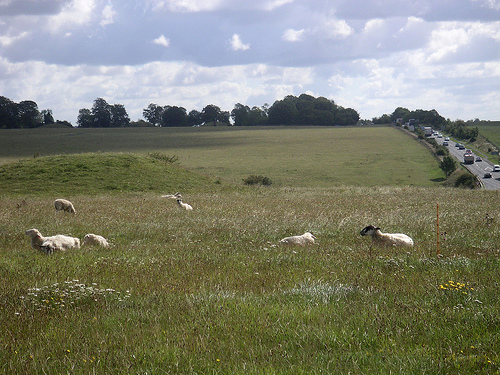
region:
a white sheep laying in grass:
[25, 225, 82, 260]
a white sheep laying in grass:
[276, 228, 317, 250]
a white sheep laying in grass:
[356, 222, 417, 253]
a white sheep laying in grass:
[170, 196, 194, 213]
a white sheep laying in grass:
[51, 198, 73, 217]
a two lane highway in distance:
[416, 116, 498, 191]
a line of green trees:
[1, 90, 362, 135]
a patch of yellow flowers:
[432, 274, 474, 302]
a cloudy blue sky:
[3, 4, 498, 114]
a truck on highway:
[460, 151, 475, 167]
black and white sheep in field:
[25, 227, 80, 257]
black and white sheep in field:
[85, 224, 106, 254]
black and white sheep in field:
[46, 189, 73, 215]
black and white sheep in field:
[162, 184, 203, 234]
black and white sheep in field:
[266, 220, 318, 256]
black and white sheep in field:
[349, 218, 409, 258]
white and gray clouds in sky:
[24, 5, 463, 82]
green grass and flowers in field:
[20, 265, 338, 346]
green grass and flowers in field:
[42, 131, 381, 188]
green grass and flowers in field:
[138, 228, 243, 312]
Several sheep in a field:
[33, 179, 419, 294]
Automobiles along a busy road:
[398, 112, 498, 190]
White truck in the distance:
[463, 149, 473, 167]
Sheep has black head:
[358, 219, 381, 232]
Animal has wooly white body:
[21, 221, 91, 253]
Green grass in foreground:
[130, 237, 496, 373]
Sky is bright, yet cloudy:
[12, 2, 495, 91]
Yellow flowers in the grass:
[436, 276, 470, 298]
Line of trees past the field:
[85, 92, 375, 126]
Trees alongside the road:
[417, 101, 482, 141]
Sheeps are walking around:
[22, 156, 457, 328]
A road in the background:
[379, 99, 499, 189]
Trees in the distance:
[28, 59, 489, 189]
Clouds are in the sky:
[26, 12, 463, 142]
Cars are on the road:
[386, 88, 498, 196]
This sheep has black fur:
[349, 200, 427, 265]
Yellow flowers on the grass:
[411, 257, 485, 322]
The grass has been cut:
[38, 176, 440, 351]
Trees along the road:
[363, 73, 485, 207]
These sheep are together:
[18, 219, 192, 273]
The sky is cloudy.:
[38, 2, 470, 91]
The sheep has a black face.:
[352, 210, 392, 253]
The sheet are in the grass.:
[33, 186, 439, 327]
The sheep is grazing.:
[76, 228, 144, 263]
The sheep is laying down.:
[275, 214, 342, 271]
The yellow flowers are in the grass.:
[433, 273, 475, 309]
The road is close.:
[392, 101, 498, 234]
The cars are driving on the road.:
[387, 91, 498, 197]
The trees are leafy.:
[50, 76, 391, 126]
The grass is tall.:
[90, 129, 268, 206]